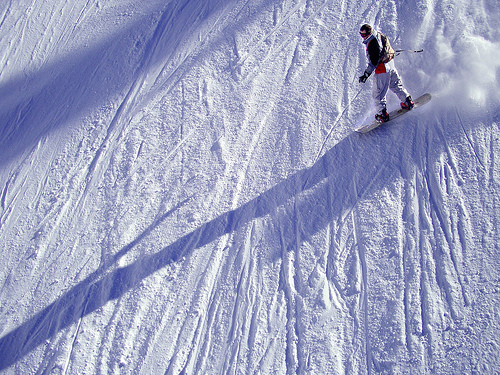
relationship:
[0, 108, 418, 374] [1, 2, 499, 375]
shadow on snow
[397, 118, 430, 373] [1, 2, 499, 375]
trail in snow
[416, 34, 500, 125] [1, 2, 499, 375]
dust kicked up from snow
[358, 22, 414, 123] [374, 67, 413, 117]
snowboarder wearing pants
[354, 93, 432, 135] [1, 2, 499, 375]
snowboard on snow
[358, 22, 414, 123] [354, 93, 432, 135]
snowboarder on snowboard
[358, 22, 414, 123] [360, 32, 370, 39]
snowboarder wearing goggles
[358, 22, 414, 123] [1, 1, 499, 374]
snowboarder going down hill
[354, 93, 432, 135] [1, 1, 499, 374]
snowboard going down hill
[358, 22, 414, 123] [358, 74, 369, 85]
snowboarder has left hand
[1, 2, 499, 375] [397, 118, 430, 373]
snow has trail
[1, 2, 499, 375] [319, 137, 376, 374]
snow has trail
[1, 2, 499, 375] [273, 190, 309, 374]
snow has trail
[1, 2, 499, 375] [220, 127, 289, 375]
snow has trail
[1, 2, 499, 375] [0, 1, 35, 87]
snow has trail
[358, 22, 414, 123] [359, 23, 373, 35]
snowboarder has hair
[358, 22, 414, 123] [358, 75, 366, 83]
snowboarder wearing glove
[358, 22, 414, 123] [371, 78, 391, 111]
snowboarder has leg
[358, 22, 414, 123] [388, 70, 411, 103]
snowboarder has leg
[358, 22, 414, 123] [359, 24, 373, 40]
snowboarder has head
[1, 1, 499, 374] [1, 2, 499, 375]
hill full of snow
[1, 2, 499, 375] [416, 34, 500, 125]
snow kicked up dust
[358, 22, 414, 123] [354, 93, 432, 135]
snowboarder on top of snowboard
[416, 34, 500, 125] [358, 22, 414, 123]
dust behind snowboarder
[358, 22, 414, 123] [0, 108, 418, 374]
snowboarder casting shadow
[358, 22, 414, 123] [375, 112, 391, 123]
snowboarder has foot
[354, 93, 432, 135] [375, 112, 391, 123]
snowboard under foot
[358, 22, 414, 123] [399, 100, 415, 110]
snowboarder has foot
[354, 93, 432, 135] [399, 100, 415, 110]
snowboard under foot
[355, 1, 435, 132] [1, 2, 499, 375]
trail in snow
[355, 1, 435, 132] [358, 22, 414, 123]
trail made by snowboarder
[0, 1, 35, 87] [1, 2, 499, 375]
trail in snow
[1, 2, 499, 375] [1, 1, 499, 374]
snow on hill